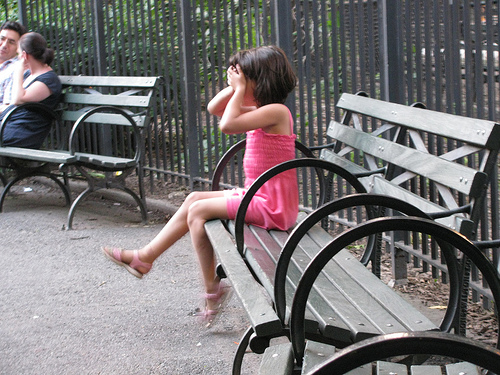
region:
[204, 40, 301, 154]
a girl holding her eyes closed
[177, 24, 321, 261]
a young girl in a pink outfit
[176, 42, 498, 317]
a young girl sitting on a bench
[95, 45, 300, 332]
a young girl wearing pink sandals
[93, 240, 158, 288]
a foot wearing sandals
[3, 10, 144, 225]
a man and a woman on a bench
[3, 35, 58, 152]
a woman wearing a black dress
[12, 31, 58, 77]
a woman wearing a pony tail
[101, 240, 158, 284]
the foot of a young girl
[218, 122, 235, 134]
the elbow of a young girl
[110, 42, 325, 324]
young girl sitting on a bench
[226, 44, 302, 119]
a young girl with short hair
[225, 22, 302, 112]
a young girl with brown hair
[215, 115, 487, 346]
a wood bench with metal frame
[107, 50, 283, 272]
a young girl wearing pink shoes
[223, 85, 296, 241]
a young girl wearing pink shorts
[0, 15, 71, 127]
a man and woman sitting on a bench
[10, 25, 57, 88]
a woman with brown hair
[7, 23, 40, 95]
a woman with her hand to her face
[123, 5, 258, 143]
a black iron fence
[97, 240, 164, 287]
a girl wearing pink color slipper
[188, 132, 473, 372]
black color sitting bench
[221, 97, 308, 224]
a girl wearing pink color frock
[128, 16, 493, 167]
a steel fencing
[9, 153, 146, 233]
stand of the sitting bench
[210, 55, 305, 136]
a girl covering her face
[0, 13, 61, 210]
a couple sitting the bench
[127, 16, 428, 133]
trees in the back of steel fencing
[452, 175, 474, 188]
bolt of the sitting bench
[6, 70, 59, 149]
a woman wearing black color dress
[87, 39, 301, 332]
girl with a pink outfit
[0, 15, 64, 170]
couple on a bench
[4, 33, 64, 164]
woman in a dark colored top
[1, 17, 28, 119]
man with dark hair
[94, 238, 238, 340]
girl's pair of sandals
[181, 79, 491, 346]
bench seating a young girl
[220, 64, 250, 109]
girl's hands on her face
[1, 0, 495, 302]
metal fence behind the benches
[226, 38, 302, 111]
girl's dark colored hair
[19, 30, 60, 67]
woman's pulled back hair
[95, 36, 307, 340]
a little girl wearing a pink dress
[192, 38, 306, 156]
girl cover his face with both hands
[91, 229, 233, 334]
pink shoes of kid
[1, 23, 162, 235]
a couple sits on a bench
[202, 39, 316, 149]
kid has short hair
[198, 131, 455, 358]
armrest of bench are circles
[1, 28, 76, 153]
woman combs with a bun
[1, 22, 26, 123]
man wears white shirt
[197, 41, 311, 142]
girl has black hair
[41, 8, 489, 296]
a fence behind benches